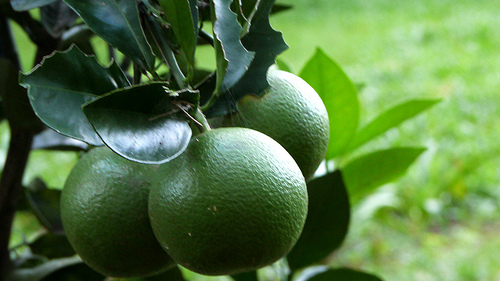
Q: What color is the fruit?
A: Green.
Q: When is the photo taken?
A: Summertime.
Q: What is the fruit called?
A: Limes.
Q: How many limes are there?
A: Three.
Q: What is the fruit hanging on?
A: A vine.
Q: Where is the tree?
A: On the left side.